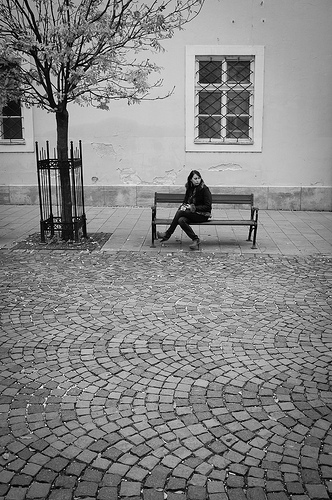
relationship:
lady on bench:
[155, 169, 213, 252] [149, 188, 259, 250]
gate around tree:
[32, 138, 89, 239] [2, 1, 210, 241]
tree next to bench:
[2, 1, 210, 241] [149, 188, 259, 250]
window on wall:
[183, 43, 262, 154] [1, 1, 329, 212]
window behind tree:
[183, 43, 262, 154] [2, 1, 210, 241]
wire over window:
[196, 52, 253, 146] [183, 43, 262, 154]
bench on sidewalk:
[149, 188, 259, 250] [0, 205, 331, 257]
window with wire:
[183, 43, 262, 154] [196, 52, 253, 146]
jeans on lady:
[167, 209, 214, 240] [155, 169, 213, 252]